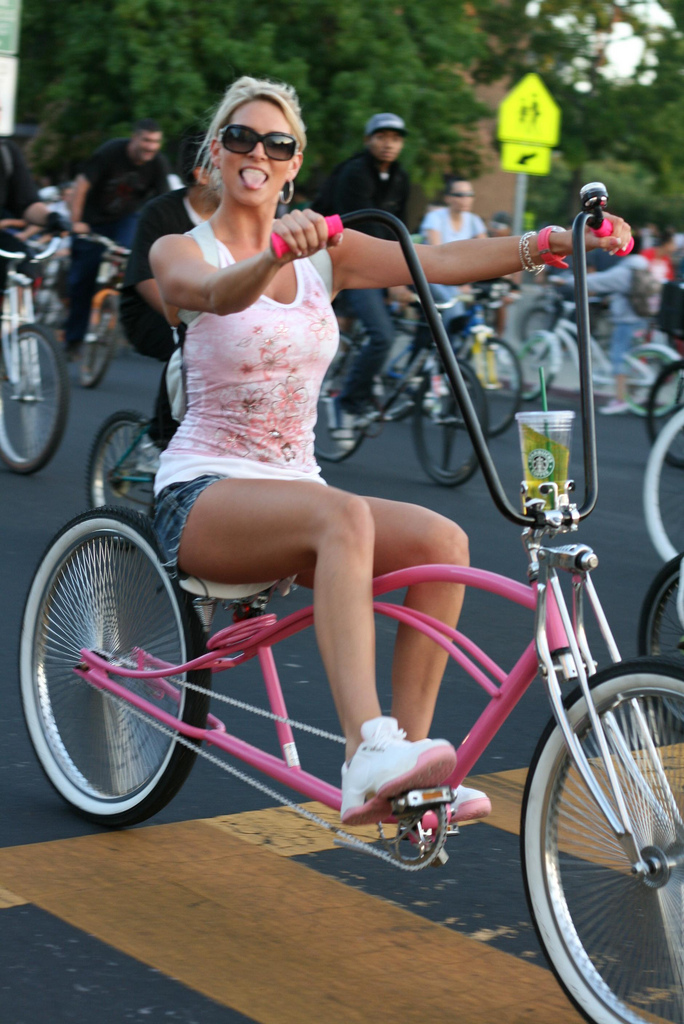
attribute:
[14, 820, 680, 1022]
line — yellow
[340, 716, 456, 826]
shoes — white , pink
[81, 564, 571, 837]
frame — pink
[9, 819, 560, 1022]
stripes — yellow 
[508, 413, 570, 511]
cup — plastic 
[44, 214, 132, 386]
bike — orange 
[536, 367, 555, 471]
straw — green 